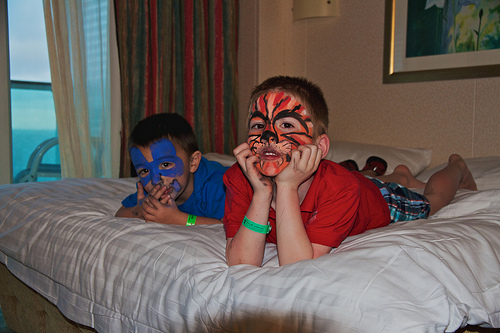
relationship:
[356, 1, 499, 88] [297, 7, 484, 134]
pitcher on wall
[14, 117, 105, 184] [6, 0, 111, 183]
chair outside window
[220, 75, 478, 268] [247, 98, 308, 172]
boy wearing face paint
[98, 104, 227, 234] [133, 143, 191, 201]
boy with face paint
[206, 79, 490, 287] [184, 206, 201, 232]
boy wears wristband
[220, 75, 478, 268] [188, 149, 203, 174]
boy has ear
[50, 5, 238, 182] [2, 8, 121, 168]
curtains on window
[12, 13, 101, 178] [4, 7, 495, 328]
window in room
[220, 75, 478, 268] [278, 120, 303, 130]
boy has eye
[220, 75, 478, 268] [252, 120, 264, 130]
boy has right eye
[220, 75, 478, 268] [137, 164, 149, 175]
boy has right eye